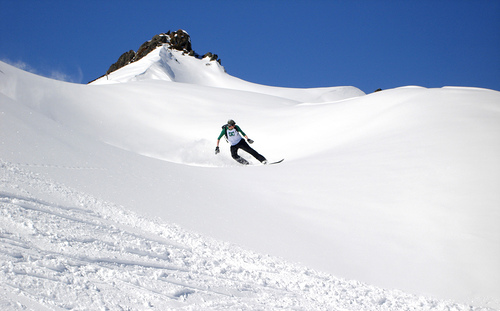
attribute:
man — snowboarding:
[210, 116, 289, 168]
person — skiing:
[210, 115, 274, 167]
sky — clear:
[5, 0, 496, 90]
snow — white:
[1, 43, 498, 309]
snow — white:
[4, 101, 499, 307]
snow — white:
[120, 195, 210, 250]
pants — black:
[226, 140, 266, 165]